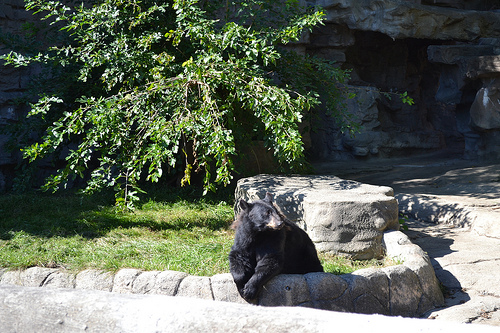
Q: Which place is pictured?
A: It is a zoo.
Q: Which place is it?
A: It is a zoo.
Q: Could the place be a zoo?
A: Yes, it is a zoo.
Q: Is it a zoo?
A: Yes, it is a zoo.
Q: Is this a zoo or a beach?
A: It is a zoo.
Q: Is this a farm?
A: No, it is a zoo.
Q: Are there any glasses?
A: No, there are no glasses.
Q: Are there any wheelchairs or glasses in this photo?
A: No, there are no glasses or wheelchairs.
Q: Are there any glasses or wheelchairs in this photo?
A: No, there are no glasses or wheelchairs.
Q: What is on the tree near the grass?
A: The leaves are on the tree.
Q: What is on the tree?
A: The leaves are on the tree.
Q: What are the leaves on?
A: The leaves are on the tree.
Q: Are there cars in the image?
A: No, there are no cars.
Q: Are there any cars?
A: No, there are no cars.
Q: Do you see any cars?
A: No, there are no cars.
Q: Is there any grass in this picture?
A: Yes, there is grass.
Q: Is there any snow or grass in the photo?
A: Yes, there is grass.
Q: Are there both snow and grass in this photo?
A: No, there is grass but no snow.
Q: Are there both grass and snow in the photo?
A: No, there is grass but no snow.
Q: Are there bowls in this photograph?
A: No, there are no bowls.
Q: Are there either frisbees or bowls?
A: No, there are no bowls or frisbees.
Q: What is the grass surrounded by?
A: The grass is surrounded by the fence.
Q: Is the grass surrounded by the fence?
A: Yes, the grass is surrounded by the fence.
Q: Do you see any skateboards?
A: No, there are no skateboards.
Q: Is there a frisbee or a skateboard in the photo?
A: No, there are no skateboards or frisbees.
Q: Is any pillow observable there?
A: No, there are no pillows.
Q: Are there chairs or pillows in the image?
A: No, there are no pillows or chairs.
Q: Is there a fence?
A: Yes, there is a fence.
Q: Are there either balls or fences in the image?
A: Yes, there is a fence.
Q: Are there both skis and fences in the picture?
A: No, there is a fence but no skis.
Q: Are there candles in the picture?
A: No, there are no candles.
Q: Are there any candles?
A: No, there are no candles.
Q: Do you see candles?
A: No, there are no candles.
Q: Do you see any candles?
A: No, there are no candles.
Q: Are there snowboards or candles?
A: No, there are no candles or snowboards.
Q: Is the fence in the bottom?
A: Yes, the fence is in the bottom of the image.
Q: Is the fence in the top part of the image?
A: No, the fence is in the bottom of the image.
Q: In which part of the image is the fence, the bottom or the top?
A: The fence is in the bottom of the image.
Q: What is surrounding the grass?
A: The fence is surrounding the grass.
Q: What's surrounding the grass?
A: The fence is surrounding the grass.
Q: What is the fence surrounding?
A: The fence is surrounding the grass.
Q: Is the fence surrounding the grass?
A: Yes, the fence is surrounding the grass.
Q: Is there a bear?
A: Yes, there is a bear.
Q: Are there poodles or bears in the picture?
A: Yes, there is a bear.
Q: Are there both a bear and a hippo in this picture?
A: No, there is a bear but no hippos.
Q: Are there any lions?
A: No, there are no lions.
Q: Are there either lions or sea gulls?
A: No, there are no lions or sea gulls.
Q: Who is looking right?
A: The bear is looking right.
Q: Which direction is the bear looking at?
A: The bear is looking right.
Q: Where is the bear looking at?
A: The bear is looking right.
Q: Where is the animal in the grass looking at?
A: The bear is looking right.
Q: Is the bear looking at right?
A: Yes, the bear is looking right.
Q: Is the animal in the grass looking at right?
A: Yes, the bear is looking right.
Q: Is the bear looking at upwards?
A: No, the bear is looking right.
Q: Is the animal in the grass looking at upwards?
A: No, the bear is looking right.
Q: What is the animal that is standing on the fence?
A: The animal is a bear.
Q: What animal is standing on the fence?
A: The animal is a bear.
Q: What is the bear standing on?
A: The bear is standing on the fence.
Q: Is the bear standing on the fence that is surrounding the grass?
A: Yes, the bear is standing on the fence.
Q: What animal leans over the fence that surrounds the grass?
A: The bear leans over the fence.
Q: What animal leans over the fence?
A: The bear leans over the fence.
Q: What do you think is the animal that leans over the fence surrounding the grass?
A: The animal is a bear.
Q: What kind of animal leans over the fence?
A: The animal is a bear.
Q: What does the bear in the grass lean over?
A: The bear leans over the fence.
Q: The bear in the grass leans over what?
A: The bear leans over the fence.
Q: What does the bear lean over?
A: The bear leans over the fence.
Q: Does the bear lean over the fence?
A: Yes, the bear leans over the fence.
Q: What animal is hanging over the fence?
A: The bear is hanging over the fence.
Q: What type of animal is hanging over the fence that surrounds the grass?
A: The animal is a bear.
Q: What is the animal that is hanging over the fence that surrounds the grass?
A: The animal is a bear.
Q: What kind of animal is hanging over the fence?
A: The animal is a bear.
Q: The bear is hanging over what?
A: The bear is hanging over the fence.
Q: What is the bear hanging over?
A: The bear is hanging over the fence.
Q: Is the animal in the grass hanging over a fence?
A: Yes, the bear is hanging over a fence.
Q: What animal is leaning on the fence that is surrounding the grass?
A: The bear is leaning on the fence.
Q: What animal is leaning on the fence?
A: The bear is leaning on the fence.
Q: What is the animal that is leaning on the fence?
A: The animal is a bear.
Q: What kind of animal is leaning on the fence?
A: The animal is a bear.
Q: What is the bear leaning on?
A: The bear is leaning on the fence.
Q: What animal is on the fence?
A: The bear is on the fence.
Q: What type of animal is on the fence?
A: The animal is a bear.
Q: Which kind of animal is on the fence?
A: The animal is a bear.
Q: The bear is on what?
A: The bear is on the fence.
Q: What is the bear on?
A: The bear is on the fence.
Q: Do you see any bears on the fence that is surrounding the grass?
A: Yes, there is a bear on the fence.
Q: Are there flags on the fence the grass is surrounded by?
A: No, there is a bear on the fence.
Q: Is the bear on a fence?
A: Yes, the bear is on a fence.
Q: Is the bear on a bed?
A: No, the bear is on a fence.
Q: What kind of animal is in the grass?
A: The animal is a bear.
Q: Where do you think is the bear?
A: The bear is in the grass.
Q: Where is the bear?
A: The bear is in the grass.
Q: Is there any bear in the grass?
A: Yes, there is a bear in the grass.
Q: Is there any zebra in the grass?
A: No, there is a bear in the grass.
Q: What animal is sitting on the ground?
A: The bear is sitting on the ground.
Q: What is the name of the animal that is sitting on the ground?
A: The animal is a bear.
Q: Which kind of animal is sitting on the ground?
A: The animal is a bear.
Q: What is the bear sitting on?
A: The bear is sitting on the ground.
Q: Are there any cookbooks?
A: No, there are no cookbooks.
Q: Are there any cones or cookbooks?
A: No, there are no cookbooks or cones.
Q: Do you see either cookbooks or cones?
A: No, there are no cookbooks or cones.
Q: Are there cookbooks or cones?
A: No, there are no cookbooks or cones.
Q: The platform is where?
A: The platform is in the grass.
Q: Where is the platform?
A: The platform is in the grass.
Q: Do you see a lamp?
A: No, there are no lamps.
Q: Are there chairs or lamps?
A: No, there are no lamps or chairs.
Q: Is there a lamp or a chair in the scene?
A: No, there are no lamps or chairs.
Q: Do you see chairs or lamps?
A: No, there are no lamps or chairs.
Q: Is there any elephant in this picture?
A: No, there are no elephants.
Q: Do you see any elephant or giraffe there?
A: No, there are no elephants or giraffes.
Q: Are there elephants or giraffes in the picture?
A: No, there are no elephants or giraffes.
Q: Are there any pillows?
A: No, there are no pillows.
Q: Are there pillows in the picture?
A: No, there are no pillows.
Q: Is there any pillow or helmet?
A: No, there are no pillows or helmets.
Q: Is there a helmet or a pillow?
A: No, there are no pillows or helmets.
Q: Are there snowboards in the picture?
A: No, there are no snowboards.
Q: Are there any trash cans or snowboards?
A: No, there are no snowboards or trash cans.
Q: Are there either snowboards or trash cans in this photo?
A: No, there are no snowboards or trash cans.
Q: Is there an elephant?
A: No, there are no elephants.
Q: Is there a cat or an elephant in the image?
A: No, there are no elephants or cats.